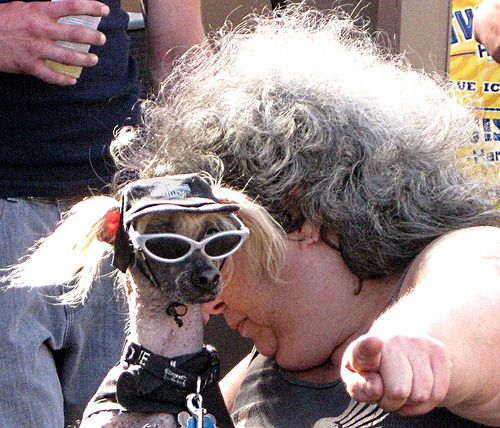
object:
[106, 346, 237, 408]
collar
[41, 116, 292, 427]
dog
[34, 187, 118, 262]
tail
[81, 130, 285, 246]
hat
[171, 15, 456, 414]
woman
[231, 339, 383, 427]
shirt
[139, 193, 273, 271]
glass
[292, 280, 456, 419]
hand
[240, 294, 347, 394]
chin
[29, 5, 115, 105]
hand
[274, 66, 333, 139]
hair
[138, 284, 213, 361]
strap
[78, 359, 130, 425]
cape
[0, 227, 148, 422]
jean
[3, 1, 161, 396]
person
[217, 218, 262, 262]
eye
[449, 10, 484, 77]
sign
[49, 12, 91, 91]
beer